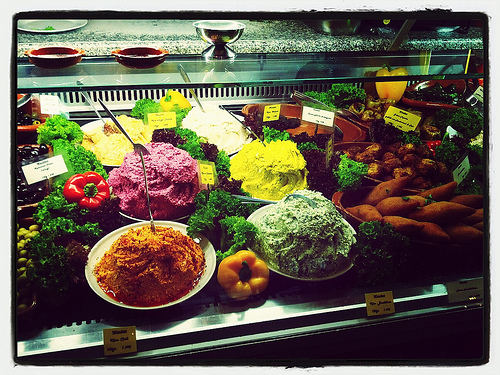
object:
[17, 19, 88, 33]
plate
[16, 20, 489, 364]
salad bar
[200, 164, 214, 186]
yellow sign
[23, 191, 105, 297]
green food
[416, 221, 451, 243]
food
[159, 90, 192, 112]
bellpepper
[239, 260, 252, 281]
green stem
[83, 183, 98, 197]
green stem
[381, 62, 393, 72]
green stem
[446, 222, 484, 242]
sweet potatoes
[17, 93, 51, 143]
brown bowl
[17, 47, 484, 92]
shelf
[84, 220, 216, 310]
bowl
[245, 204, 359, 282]
bowl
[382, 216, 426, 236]
food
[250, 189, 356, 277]
food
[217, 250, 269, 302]
bell pepper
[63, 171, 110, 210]
bell pepper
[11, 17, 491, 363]
case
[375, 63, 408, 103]
bell pepper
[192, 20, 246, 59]
bowl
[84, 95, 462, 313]
on display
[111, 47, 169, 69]
bowl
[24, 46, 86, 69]
bowl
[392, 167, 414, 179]
food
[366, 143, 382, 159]
food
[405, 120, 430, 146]
ground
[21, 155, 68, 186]
sign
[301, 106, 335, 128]
sign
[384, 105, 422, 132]
sign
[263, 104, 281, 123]
sign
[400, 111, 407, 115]
lettering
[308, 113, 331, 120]
lettering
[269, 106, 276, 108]
lettering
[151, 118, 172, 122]
lettering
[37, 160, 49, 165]
lettering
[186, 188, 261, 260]
kale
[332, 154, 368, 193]
kale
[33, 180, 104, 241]
kale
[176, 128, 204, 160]
kale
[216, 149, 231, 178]
kale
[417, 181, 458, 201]
food item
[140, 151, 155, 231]
utensil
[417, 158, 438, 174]
food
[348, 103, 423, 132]
bowl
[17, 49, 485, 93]
counter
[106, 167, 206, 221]
bowl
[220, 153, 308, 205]
bowl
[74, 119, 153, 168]
bowl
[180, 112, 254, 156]
bowl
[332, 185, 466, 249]
bowl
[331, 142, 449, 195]
bowl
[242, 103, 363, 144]
bowl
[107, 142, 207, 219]
food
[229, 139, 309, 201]
food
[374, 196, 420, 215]
food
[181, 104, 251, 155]
food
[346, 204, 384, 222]
food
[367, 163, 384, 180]
food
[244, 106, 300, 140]
food